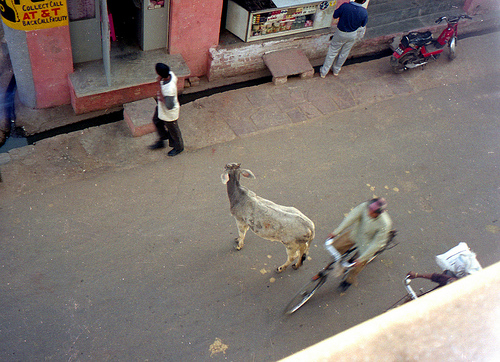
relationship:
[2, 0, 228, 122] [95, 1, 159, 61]
storefront with doorway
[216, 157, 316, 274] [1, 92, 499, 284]
animal standing on street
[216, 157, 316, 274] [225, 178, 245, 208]
animal with neck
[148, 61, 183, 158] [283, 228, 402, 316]
man riding bicycle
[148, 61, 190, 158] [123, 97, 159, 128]
man standing by step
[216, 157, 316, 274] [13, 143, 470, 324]
animal standing on street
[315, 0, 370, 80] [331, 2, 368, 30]
person wearing shirt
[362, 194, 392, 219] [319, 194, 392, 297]
head of person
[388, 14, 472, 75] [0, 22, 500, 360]
bike on road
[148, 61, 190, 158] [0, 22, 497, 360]
man on road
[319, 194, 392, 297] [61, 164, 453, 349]
person on road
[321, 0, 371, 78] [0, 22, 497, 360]
person on road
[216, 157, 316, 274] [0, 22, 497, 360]
animal on road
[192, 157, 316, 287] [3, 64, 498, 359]
animal on street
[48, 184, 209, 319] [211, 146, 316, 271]
street next to animal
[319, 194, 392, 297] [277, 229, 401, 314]
person riding bicycle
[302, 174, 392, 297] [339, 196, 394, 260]
person wearing shirt